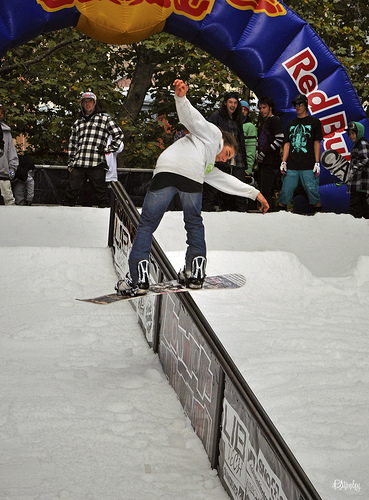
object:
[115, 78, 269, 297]
man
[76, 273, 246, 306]
board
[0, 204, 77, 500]
snow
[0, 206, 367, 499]
ground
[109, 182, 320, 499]
rail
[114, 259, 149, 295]
boot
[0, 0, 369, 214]
sign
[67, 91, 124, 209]
person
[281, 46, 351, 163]
logo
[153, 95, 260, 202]
shirt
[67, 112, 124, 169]
jacket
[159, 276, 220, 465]
sign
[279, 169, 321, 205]
shorts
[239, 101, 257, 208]
person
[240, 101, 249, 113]
hat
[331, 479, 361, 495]
name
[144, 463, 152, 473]
spot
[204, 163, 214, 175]
logo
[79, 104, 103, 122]
fur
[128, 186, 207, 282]
jeans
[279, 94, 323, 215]
man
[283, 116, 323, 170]
black and green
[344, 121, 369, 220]
boy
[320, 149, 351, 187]
board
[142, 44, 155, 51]
leaf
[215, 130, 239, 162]
head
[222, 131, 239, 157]
hair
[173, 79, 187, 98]
hand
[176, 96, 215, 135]
arm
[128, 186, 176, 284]
leg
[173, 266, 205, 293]
foot